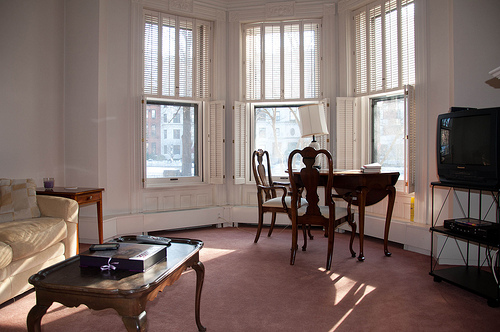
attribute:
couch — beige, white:
[8, 152, 108, 261]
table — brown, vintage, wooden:
[42, 216, 206, 330]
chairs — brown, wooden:
[249, 137, 362, 234]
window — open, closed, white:
[129, 7, 437, 209]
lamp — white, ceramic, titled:
[288, 77, 335, 173]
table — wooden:
[264, 154, 403, 215]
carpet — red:
[211, 224, 299, 280]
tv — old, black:
[419, 102, 492, 191]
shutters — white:
[147, 14, 401, 101]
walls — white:
[17, 35, 132, 146]